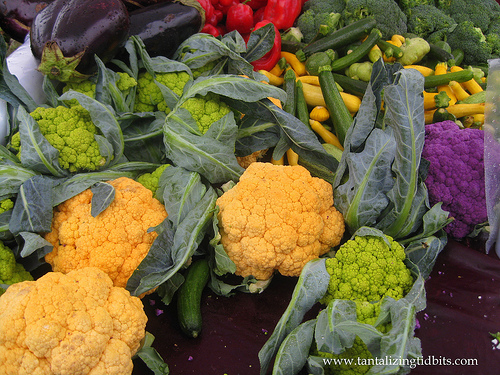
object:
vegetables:
[0, 0, 500, 375]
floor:
[424, 245, 500, 375]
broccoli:
[369, 0, 408, 36]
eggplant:
[0, 0, 206, 79]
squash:
[316, 67, 355, 144]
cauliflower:
[317, 329, 376, 375]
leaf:
[256, 258, 331, 375]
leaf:
[271, 319, 312, 375]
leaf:
[369, 274, 427, 374]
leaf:
[311, 300, 381, 353]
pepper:
[197, 0, 304, 72]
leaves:
[119, 188, 219, 295]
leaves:
[9, 172, 55, 235]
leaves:
[334, 58, 454, 243]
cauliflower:
[23, 177, 171, 301]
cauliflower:
[213, 160, 347, 279]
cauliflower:
[326, 227, 411, 331]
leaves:
[161, 107, 251, 186]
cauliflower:
[416, 115, 499, 236]